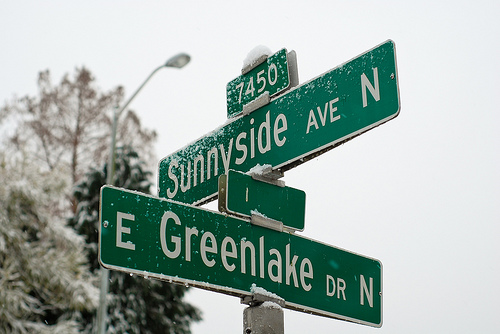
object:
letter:
[359, 274, 373, 308]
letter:
[159, 211, 182, 259]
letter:
[200, 231, 218, 267]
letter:
[240, 240, 256, 276]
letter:
[166, 109, 288, 198]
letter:
[305, 97, 340, 133]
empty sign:
[220, 169, 306, 232]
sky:
[3, 2, 496, 332]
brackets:
[251, 166, 287, 188]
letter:
[220, 236, 238, 272]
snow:
[239, 42, 273, 67]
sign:
[225, 47, 290, 119]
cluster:
[98, 39, 402, 333]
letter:
[184, 227, 198, 261]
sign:
[98, 184, 385, 328]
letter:
[360, 67, 381, 108]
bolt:
[103, 219, 110, 228]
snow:
[0, 66, 157, 330]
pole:
[95, 64, 169, 334]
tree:
[0, 63, 206, 333]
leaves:
[108, 283, 185, 324]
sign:
[156, 39, 401, 206]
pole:
[241, 52, 284, 334]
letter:
[236, 64, 289, 104]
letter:
[115, 211, 135, 251]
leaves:
[76, 84, 103, 109]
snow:
[28, 97, 75, 256]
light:
[95, 52, 191, 332]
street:
[0, 55, 500, 334]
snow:
[0, 95, 145, 334]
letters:
[326, 274, 347, 301]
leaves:
[9, 142, 35, 178]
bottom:
[239, 283, 286, 307]